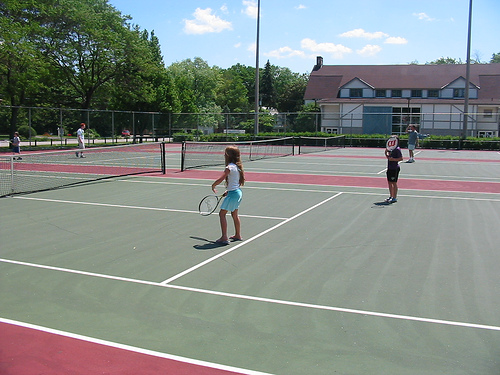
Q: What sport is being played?
A: Tennis.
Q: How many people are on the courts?
A: 5.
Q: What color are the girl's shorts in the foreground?
A: Blue.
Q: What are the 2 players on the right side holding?
A: Tennis rackets.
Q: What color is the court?
A: Green.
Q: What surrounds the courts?
A: Fence.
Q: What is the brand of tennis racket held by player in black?
A: Wilson.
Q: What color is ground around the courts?
A: Red.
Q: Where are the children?
A: A tennis court.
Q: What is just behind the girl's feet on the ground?
A: White line.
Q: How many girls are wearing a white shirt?
A: One.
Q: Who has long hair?
A: Girl with blue shorts.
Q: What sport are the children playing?
A: Tennis.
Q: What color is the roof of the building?
A: Red.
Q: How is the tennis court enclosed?
A: By a fence.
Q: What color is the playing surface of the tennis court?
A: Green.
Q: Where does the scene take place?
A: On a tennis court.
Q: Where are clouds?
A: In the sky.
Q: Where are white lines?
A: On the court.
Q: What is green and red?
A: The court.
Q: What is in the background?
A: Trees.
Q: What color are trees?
A: Green.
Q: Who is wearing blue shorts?
A: Blonde girl.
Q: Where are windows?
A: On a white building.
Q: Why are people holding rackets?
A: To play tennis.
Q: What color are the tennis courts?
A: Green.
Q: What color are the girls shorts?
A: Blue.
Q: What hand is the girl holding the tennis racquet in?
A: Left.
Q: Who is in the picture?
A: Tennis players.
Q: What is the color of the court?
A: Green.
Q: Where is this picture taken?
A: The tennis court.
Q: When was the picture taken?
A: Daytime.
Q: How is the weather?
A: Sunny.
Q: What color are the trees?
A: Green.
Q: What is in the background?
A: A building.